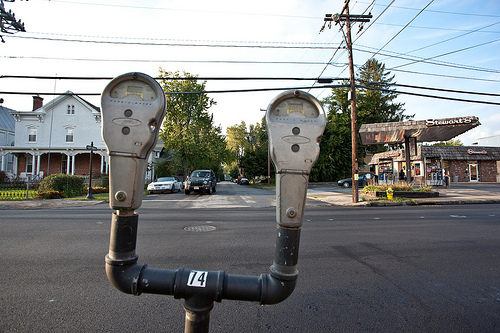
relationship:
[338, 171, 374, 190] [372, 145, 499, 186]
car parked at store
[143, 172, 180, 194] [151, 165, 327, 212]
car on road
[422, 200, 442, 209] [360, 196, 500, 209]
storm drain at curb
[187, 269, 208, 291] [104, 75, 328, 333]
74 on meters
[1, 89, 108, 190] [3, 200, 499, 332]
house on street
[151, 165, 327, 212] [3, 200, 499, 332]
road off street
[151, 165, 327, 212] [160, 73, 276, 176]
road has trees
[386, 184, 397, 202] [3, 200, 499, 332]
hydrant on street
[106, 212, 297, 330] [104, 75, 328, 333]
pipe holds meters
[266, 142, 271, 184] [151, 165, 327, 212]
post on road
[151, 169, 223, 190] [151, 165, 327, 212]
vehicles on road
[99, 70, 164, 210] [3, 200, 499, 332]
parking meter on street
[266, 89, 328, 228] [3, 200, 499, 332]
parking meter on street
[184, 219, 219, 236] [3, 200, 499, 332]
sewer cover in street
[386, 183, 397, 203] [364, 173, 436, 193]
hydrant by tall grass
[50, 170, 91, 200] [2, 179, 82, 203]
bush by fence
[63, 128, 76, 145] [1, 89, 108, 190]
window on house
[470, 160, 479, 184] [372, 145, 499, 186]
door on store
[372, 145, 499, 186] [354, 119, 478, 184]
store has gas pumps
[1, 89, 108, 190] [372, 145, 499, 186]
house across from store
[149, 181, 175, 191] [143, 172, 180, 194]
headlights on a car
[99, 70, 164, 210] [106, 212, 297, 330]
parking meter mounted to a pipe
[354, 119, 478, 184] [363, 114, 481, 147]
gas pumps has brown roof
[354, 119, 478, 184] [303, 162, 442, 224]
gas pumps on corner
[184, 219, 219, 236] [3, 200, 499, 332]
manhole in street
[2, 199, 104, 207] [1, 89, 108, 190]
sidewalk in front of house